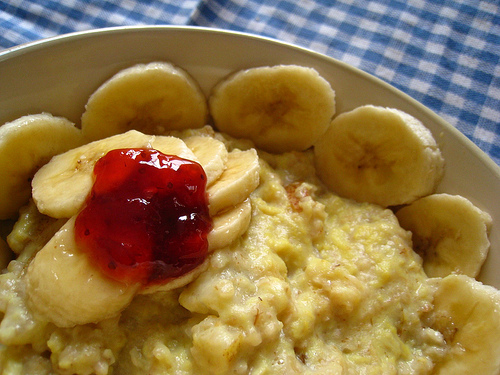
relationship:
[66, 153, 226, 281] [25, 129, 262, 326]
jam on some bananas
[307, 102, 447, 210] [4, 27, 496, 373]
banana around bowl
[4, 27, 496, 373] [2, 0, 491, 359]
bowl on table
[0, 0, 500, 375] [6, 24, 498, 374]
table on table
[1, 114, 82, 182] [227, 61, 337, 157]
bananas cut into circles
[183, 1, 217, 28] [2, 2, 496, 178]
crease in tablecloth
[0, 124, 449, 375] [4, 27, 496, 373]
chunk in bowl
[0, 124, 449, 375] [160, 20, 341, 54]
chunk in bowl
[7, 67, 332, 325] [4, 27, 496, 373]
bananas in bowl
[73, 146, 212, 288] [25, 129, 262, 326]
jam on top bananas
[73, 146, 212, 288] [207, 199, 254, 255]
jam on bananas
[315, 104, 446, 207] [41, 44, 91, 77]
banana on bowl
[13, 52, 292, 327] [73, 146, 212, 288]
bananas with jam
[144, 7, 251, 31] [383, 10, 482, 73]
crease in tablecloth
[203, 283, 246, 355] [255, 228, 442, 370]
chunk in oatmeal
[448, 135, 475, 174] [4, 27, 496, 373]
part of bowl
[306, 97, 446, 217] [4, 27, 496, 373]
banana in a bowl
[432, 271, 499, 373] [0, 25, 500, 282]
banana in a bowl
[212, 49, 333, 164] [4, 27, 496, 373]
banana in a bowl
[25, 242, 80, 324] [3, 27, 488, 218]
banana inside of bowl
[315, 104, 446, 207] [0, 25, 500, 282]
banana inside of bowl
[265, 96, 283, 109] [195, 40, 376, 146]
seed in center of banana slice